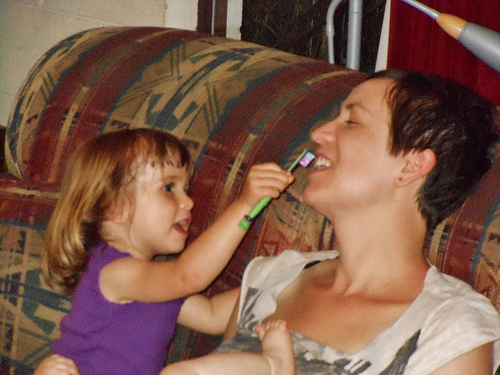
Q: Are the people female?
A: Yes, all the people are female.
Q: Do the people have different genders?
A: No, all the people are female.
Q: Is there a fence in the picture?
A: No, there are no fences.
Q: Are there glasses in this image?
A: No, there are no glasses.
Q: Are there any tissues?
A: No, there are no tissues.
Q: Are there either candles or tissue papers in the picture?
A: No, there are no tissue papers or candles.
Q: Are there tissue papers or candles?
A: No, there are no tissue papers or candles.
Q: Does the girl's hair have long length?
A: Yes, the hair is long.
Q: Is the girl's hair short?
A: No, the hair is long.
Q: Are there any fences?
A: No, there are no fences.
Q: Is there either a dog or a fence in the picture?
A: No, there are no fences or dogs.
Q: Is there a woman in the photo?
A: Yes, there is a woman.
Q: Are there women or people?
A: Yes, there is a woman.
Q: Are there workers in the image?
A: No, there are no workers.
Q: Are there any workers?
A: No, there are no workers.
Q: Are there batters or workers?
A: No, there are no workers or batters.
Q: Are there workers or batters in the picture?
A: No, there are no workers or batters.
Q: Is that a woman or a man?
A: That is a woman.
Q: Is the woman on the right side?
A: Yes, the woman is on the right of the image.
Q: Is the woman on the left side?
A: No, the woman is on the right of the image.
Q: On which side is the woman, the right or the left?
A: The woman is on the right of the image.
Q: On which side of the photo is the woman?
A: The woman is on the right of the image.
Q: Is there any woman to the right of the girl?
A: Yes, there is a woman to the right of the girl.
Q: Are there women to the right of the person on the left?
A: Yes, there is a woman to the right of the girl.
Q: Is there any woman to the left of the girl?
A: No, the woman is to the right of the girl.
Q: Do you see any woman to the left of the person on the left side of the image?
A: No, the woman is to the right of the girl.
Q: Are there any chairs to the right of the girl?
A: No, there is a woman to the right of the girl.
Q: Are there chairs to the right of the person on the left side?
A: No, there is a woman to the right of the girl.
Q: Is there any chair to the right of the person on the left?
A: No, there is a woman to the right of the girl.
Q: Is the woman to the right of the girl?
A: Yes, the woman is to the right of the girl.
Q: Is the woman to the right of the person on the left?
A: Yes, the woman is to the right of the girl.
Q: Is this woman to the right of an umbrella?
A: No, the woman is to the right of the girl.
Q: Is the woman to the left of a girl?
A: No, the woman is to the right of a girl.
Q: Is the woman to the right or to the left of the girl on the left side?
A: The woman is to the right of the girl.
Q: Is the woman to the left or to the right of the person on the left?
A: The woman is to the right of the girl.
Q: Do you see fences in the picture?
A: No, there are no fences.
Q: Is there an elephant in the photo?
A: No, there are no elephants.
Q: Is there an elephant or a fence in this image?
A: No, there are no elephants or fences.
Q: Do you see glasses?
A: No, there are no glasses.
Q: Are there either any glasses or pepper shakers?
A: No, there are no glasses or pepper shakers.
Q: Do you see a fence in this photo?
A: No, there are no fences.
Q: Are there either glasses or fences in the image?
A: No, there are no fences or glasses.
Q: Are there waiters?
A: No, there are no waiters.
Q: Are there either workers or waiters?
A: No, there are no waiters or workers.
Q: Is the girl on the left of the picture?
A: Yes, the girl is on the left of the image.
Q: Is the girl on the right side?
A: No, the girl is on the left of the image.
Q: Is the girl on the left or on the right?
A: The girl is on the left of the image.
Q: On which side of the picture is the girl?
A: The girl is on the left of the image.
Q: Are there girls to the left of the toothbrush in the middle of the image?
A: Yes, there is a girl to the left of the toothbrush.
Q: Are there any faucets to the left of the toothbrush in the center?
A: No, there is a girl to the left of the toothbrush.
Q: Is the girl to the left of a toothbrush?
A: Yes, the girl is to the left of a toothbrush.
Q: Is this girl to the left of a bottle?
A: No, the girl is to the left of a toothbrush.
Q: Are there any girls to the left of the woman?
A: Yes, there is a girl to the left of the woman.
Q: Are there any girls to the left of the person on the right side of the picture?
A: Yes, there is a girl to the left of the woman.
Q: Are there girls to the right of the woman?
A: No, the girl is to the left of the woman.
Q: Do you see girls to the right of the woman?
A: No, the girl is to the left of the woman.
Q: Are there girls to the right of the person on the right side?
A: No, the girl is to the left of the woman.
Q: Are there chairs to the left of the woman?
A: No, there is a girl to the left of the woman.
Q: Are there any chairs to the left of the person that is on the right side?
A: No, there is a girl to the left of the woman.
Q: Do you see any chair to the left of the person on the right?
A: No, there is a girl to the left of the woman.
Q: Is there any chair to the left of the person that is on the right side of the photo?
A: No, there is a girl to the left of the woman.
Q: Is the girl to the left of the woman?
A: Yes, the girl is to the left of the woman.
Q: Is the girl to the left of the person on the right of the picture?
A: Yes, the girl is to the left of the woman.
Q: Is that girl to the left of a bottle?
A: No, the girl is to the left of the woman.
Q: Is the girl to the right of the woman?
A: No, the girl is to the left of the woman.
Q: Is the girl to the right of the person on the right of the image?
A: No, the girl is to the left of the woman.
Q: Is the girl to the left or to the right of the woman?
A: The girl is to the left of the woman.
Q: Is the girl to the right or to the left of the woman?
A: The girl is to the left of the woman.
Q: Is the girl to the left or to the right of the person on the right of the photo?
A: The girl is to the left of the woman.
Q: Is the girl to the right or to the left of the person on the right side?
A: The girl is to the left of the woman.